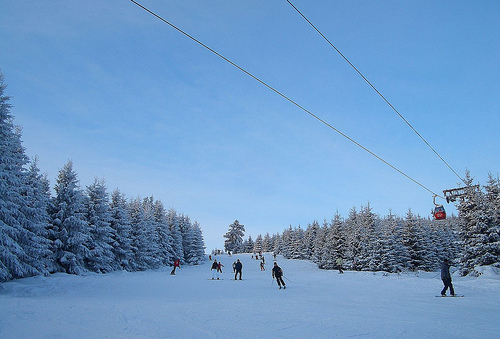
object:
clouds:
[0, 0, 500, 234]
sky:
[0, 0, 499, 255]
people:
[335, 255, 344, 274]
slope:
[0, 251, 500, 339]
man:
[271, 261, 286, 290]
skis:
[283, 286, 287, 290]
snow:
[1, 73, 500, 339]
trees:
[316, 209, 360, 275]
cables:
[280, 0, 472, 188]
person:
[170, 258, 181, 275]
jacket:
[174, 259, 179, 267]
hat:
[273, 261, 277, 264]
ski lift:
[431, 195, 447, 221]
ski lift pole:
[443, 181, 483, 204]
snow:
[0, 73, 51, 282]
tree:
[41, 157, 96, 279]